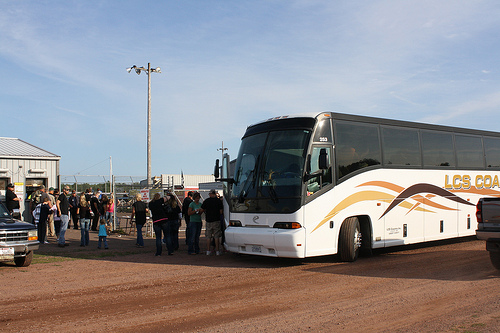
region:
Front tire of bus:
[330, 208, 369, 261]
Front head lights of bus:
[226, 214, 306, 234]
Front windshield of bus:
[230, 127, 315, 196]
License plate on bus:
[247, 240, 267, 257]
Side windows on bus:
[335, 118, 498, 188]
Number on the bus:
[315, 129, 330, 144]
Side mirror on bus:
[305, 145, 335, 187]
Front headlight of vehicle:
[22, 225, 41, 242]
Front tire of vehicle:
[13, 244, 35, 270]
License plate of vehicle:
[0, 243, 17, 260]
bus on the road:
[219, 110, 496, 261]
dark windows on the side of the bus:
[328, 114, 499, 193]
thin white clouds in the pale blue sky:
[1, 0, 496, 192]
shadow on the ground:
[17, 215, 306, 273]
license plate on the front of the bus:
[247, 243, 265, 255]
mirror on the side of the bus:
[313, 145, 332, 175]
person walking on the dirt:
[126, 190, 150, 245]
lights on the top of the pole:
[121, 61, 165, 79]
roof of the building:
[0, 132, 60, 160]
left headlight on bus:
[276, 220, 301, 234]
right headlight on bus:
[227, 220, 242, 231]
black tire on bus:
[340, 215, 361, 263]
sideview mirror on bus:
[316, 145, 333, 177]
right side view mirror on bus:
[206, 157, 229, 185]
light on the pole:
[126, 58, 168, 81]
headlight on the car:
[25, 231, 39, 243]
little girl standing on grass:
[91, 218, 113, 248]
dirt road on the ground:
[3, 260, 479, 330]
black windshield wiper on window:
[237, 161, 258, 201]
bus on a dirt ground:
[213, 111, 499, 264]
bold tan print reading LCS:
[442, 173, 472, 190]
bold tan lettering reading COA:
[473, 173, 498, 190]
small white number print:
[317, 135, 329, 142]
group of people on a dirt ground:
[25, 183, 225, 257]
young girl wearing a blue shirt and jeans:
[95, 218, 112, 252]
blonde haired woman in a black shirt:
[127, 190, 149, 245]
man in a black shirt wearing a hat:
[55, 182, 75, 248]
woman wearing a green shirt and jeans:
[186, 190, 206, 255]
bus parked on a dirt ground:
[211, 110, 498, 261]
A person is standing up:
[148, 189, 174, 258]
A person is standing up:
[188, 192, 199, 259]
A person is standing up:
[203, 189, 218, 255]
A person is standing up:
[131, 182, 151, 242]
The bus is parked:
[219, 108, 499, 257]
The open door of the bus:
[220, 151, 232, 237]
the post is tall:
[144, 61, 152, 194]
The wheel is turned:
[337, 216, 363, 259]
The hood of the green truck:
[1, 216, 40, 256]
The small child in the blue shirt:
[95, 216, 111, 252]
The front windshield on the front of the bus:
[231, 129, 310, 196]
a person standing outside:
[188, 197, 207, 249]